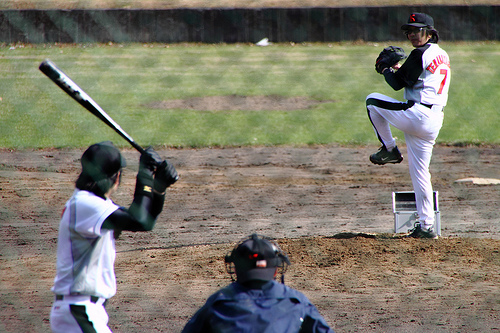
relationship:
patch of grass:
[86, 74, 146, 110] [0, 40, 499, 142]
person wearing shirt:
[204, 227, 323, 330] [176, 279, 329, 330]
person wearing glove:
[42, 135, 177, 331] [134, 146, 181, 186]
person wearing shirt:
[42, 135, 177, 331] [50, 184, 137, 297]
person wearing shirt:
[364, 11, 450, 240] [416, 44, 482, 103]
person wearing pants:
[364, 11, 451, 237] [365, 91, 443, 233]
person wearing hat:
[42, 135, 177, 331] [400, 7, 447, 36]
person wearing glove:
[364, 11, 450, 240] [364, 40, 412, 82]